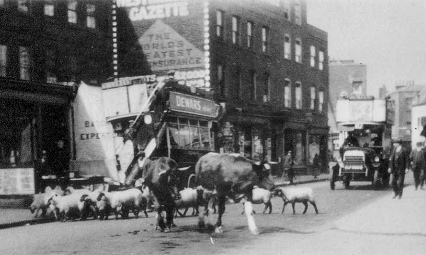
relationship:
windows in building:
[212, 21, 336, 76] [182, 14, 365, 165]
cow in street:
[194, 152, 282, 236] [1, 168, 425, 253]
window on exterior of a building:
[16, 40, 37, 80] [0, 0, 118, 190]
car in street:
[327, 100, 406, 195] [320, 189, 378, 228]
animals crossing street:
[251, 181, 322, 213] [84, 173, 371, 239]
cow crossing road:
[132, 140, 285, 235] [83, 173, 421, 251]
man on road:
[386, 138, 410, 199] [0, 172, 425, 254]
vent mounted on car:
[342, 155, 365, 170] [327, 100, 406, 195]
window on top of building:
[317, 48, 324, 70] [111, 0, 329, 173]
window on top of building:
[294, 36, 302, 64] [111, 0, 329, 173]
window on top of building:
[259, 24, 269, 55] [111, 0, 329, 173]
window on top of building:
[246, 19, 254, 52] [111, 0, 329, 173]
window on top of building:
[216, 9, 223, 37] [111, 0, 329, 173]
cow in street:
[142, 152, 282, 235] [37, 140, 394, 250]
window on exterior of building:
[214, 8, 230, 42] [5, 18, 345, 206]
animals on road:
[272, 186, 318, 214] [0, 172, 425, 254]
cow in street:
[191, 148, 285, 244] [3, 153, 400, 253]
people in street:
[384, 134, 425, 199] [18, 154, 407, 246]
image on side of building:
[110, 4, 220, 103] [121, 10, 340, 182]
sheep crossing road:
[38, 167, 328, 223] [15, 149, 393, 253]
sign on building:
[151, 77, 267, 122] [6, 17, 342, 185]